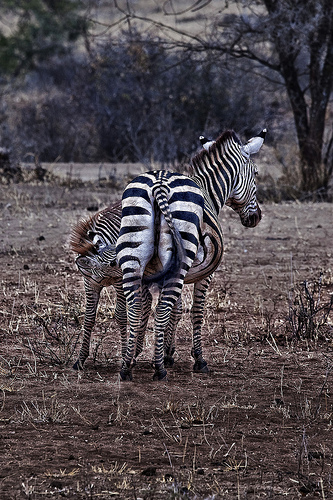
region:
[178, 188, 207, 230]
blue and white stripes on zebra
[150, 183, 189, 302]
long tail on the zebra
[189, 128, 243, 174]
comb on back of zebra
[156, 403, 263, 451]
twigs on the ground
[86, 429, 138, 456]
brown dirt on the ground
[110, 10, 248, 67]
branches on the tree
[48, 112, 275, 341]
zebra standing in the field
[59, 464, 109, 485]
Small patch of brush on the ground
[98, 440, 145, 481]
Small patch of brush on the ground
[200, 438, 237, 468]
Small patch of brush on the ground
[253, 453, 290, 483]
Small patch of brush on the ground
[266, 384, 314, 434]
Small patch of brush on the ground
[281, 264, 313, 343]
Small patch of brush on the ground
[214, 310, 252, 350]
Small patch of brush on the ground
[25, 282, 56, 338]
Small patch of brush on the ground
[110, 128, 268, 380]
A mother Zebra feeds her young.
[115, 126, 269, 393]
A mother zebra with her young.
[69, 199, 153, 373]
A young zebra feeds from its mother.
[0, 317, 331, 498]
A vast amount of barren grassland.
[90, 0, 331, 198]
A large tree stands tall and leafless.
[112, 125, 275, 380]
A mother zebra stands still on the ground.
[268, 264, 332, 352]
A patch of thistle grows from ground.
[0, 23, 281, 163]
A blurry patch of trees in the background.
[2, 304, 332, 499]
Lots of dead grass in the foreground.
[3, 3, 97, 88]
A tree that still has some green leaves on it.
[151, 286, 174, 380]
leg of a zebra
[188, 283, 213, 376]
leg of a zebra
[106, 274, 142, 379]
leg of a zebra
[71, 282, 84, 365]
leg of a zebra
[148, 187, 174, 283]
tail of a zebra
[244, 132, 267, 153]
ear of a zebra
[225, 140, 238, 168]
stripes on a zebra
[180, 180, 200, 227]
stripes of a zebra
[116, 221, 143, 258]
stripes on a zebra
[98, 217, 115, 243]
stripes on a zebra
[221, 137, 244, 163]
Black and white stripes on a zebra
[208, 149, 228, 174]
Black and white stripes on a zebra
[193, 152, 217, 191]
Black and white stripes on a zebra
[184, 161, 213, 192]
Black and white stripes on a zebra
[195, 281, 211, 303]
Black and white stripes on a zebra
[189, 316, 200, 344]
Black and white stripes on a zebra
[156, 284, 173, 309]
Black and white stripes on a zebra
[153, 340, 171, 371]
Black and white stripes on a zebra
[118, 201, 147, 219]
Black stripe on a zebra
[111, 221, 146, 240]
Black stripe on a zebra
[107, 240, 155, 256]
Black stripe on a zebra